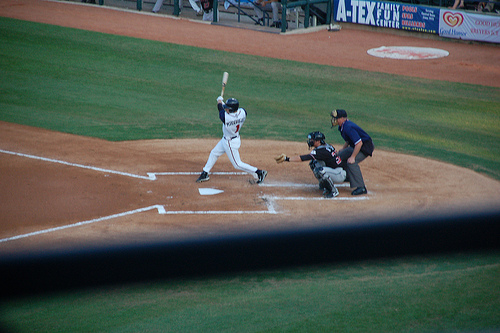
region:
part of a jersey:
[235, 129, 248, 156]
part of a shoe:
[334, 204, 348, 244]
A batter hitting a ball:
[193, 57, 270, 178]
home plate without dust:
[181, 165, 258, 235]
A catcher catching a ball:
[280, 104, 365, 196]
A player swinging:
[136, 49, 410, 202]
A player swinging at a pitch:
[172, 62, 272, 192]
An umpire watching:
[308, 70, 387, 233]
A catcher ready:
[267, 116, 351, 206]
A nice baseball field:
[359, 57, 479, 132]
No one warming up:
[357, 28, 453, 78]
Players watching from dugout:
[181, 5, 304, 32]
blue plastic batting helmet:
[226, 97, 239, 109]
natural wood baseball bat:
[219, 68, 229, 99]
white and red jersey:
[221, 109, 246, 141]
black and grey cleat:
[256, 168, 268, 186]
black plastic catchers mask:
[307, 129, 324, 147]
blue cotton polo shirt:
[339, 121, 371, 152]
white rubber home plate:
[198, 187, 222, 197]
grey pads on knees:
[311, 162, 333, 194]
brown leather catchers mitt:
[272, 152, 287, 166]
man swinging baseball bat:
[196, 69, 268, 187]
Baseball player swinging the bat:
[188, 65, 270, 185]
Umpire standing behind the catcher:
[270, 96, 382, 198]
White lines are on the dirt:
[0, 140, 375, 245]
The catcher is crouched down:
[265, 125, 347, 201]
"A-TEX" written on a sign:
[330, 0, 377, 30]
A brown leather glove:
[265, 145, 290, 166]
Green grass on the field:
[0, 10, 495, 330]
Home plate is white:
[192, 180, 227, 200]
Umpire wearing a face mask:
[320, 100, 350, 130]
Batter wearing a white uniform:
[196, 90, 257, 187]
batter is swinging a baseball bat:
[193, 69, 268, 186]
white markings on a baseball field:
[0, 139, 366, 247]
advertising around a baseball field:
[331, 0, 498, 48]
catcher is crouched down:
[273, 128, 348, 197]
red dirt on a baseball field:
[1, 115, 497, 282]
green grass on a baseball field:
[3, 15, 499, 177]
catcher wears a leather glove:
[271, 130, 351, 200]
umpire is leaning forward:
[324, 105, 378, 195]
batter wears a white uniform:
[195, 67, 269, 189]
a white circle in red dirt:
[364, 38, 454, 68]